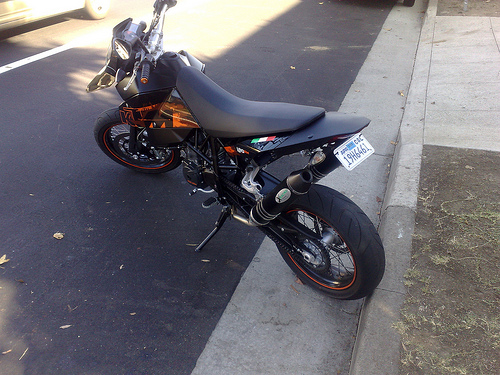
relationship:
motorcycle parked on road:
[77, 0, 386, 299] [0, 0, 431, 374]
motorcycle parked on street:
[77, 0, 386, 299] [1, 1, 428, 371]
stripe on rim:
[285, 204, 357, 290] [279, 207, 363, 297]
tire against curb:
[270, 172, 414, 322] [296, 306, 398, 374]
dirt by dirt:
[397, 143, 500, 374] [397, 143, 497, 373]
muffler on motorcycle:
[245, 166, 315, 230] [77, 0, 386, 299]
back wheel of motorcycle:
[269, 183, 386, 302] [77, 0, 386, 299]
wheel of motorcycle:
[91, 107, 192, 192] [62, 16, 428, 327]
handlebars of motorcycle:
[82, 1, 174, 95] [92, 50, 444, 322]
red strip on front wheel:
[124, 102, 176, 125] [85, 102, 183, 177]